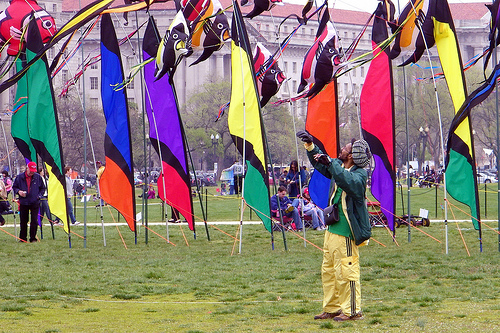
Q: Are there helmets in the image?
A: No, there are no helmets.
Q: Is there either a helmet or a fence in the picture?
A: No, there are no helmets or fences.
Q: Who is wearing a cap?
A: The man is wearing a cap.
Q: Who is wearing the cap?
A: The man is wearing a cap.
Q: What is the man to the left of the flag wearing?
A: The man is wearing a cap.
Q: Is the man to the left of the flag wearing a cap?
A: Yes, the man is wearing a cap.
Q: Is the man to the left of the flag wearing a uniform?
A: No, the man is wearing a cap.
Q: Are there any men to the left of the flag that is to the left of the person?
A: Yes, there is a man to the left of the flag.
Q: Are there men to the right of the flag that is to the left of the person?
A: No, the man is to the left of the flag.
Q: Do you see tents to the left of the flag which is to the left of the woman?
A: No, there is a man to the left of the flag.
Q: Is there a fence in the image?
A: No, there are no fences.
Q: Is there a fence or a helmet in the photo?
A: No, there are no fences or helmets.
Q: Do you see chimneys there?
A: No, there are no chimneys.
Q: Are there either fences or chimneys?
A: No, there are no chimneys or fences.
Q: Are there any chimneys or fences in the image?
A: No, there are no chimneys or fences.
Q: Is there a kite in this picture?
A: Yes, there is a kite.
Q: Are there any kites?
A: Yes, there is a kite.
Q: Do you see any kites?
A: Yes, there is a kite.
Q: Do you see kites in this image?
A: Yes, there is a kite.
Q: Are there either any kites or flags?
A: Yes, there is a kite.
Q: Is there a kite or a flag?
A: Yes, there is a kite.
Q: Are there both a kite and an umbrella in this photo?
A: No, there is a kite but no umbrellas.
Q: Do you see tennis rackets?
A: No, there are no tennis rackets.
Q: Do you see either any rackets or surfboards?
A: No, there are no rackets or surfboards.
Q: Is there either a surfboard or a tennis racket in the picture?
A: No, there are no rackets or surfboards.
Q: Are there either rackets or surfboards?
A: No, there are no rackets or surfboards.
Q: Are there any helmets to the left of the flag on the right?
A: No, there is a kite to the left of the flag.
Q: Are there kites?
A: Yes, there is a kite.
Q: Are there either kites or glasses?
A: Yes, there is a kite.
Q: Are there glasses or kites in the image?
A: Yes, there is a kite.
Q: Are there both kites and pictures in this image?
A: No, there is a kite but no pictures.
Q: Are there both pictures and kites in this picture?
A: No, there is a kite but no pictures.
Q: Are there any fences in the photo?
A: No, there are no fences.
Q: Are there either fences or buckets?
A: No, there are no fences or buckets.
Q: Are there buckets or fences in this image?
A: No, there are no fences or buckets.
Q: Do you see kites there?
A: Yes, there is a kite.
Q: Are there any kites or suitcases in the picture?
A: Yes, there is a kite.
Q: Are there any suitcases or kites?
A: Yes, there is a kite.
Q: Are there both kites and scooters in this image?
A: No, there is a kite but no scooters.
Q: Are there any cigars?
A: No, there are no cigars.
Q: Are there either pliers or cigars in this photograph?
A: No, there are no cigars or pliers.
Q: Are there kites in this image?
A: Yes, there is a kite.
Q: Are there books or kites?
A: Yes, there is a kite.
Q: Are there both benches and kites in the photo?
A: Yes, there are both a kite and a bench.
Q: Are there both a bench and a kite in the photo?
A: Yes, there are both a kite and a bench.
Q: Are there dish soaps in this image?
A: No, there are no dish soaps.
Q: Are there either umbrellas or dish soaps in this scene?
A: No, there are no dish soaps or umbrellas.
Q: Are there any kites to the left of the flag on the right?
A: Yes, there is a kite to the left of the flag.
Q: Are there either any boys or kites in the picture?
A: Yes, there is a kite.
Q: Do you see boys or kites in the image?
A: Yes, there is a kite.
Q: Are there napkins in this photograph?
A: No, there are no napkins.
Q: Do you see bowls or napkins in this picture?
A: No, there are no napkins or bowls.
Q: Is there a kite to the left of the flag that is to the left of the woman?
A: Yes, there is a kite to the left of the flag.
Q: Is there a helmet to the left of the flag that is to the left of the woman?
A: No, there is a kite to the left of the flag.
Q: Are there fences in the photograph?
A: No, there are no fences.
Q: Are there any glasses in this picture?
A: No, there are no glasses.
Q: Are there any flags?
A: Yes, there is a flag.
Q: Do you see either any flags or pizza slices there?
A: Yes, there is a flag.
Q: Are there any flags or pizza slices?
A: Yes, there is a flag.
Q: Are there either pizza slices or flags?
A: Yes, there is a flag.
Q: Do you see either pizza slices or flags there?
A: Yes, there is a flag.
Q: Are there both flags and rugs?
A: No, there is a flag but no rugs.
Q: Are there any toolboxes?
A: No, there are no toolboxes.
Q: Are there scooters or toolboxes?
A: No, there are no toolboxes or scooters.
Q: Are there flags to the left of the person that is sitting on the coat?
A: Yes, there is a flag to the left of the person.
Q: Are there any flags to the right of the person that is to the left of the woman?
A: No, the flag is to the left of the person.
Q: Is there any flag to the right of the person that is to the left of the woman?
A: No, the flag is to the left of the person.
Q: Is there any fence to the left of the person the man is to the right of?
A: No, there is a flag to the left of the person.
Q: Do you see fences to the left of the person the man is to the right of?
A: No, there is a flag to the left of the person.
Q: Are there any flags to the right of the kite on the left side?
A: Yes, there is a flag to the right of the kite.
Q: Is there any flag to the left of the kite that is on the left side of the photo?
A: No, the flag is to the right of the kite.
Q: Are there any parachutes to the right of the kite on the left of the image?
A: No, there is a flag to the right of the kite.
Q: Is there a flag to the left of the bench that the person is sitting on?
A: Yes, there is a flag to the left of the bench.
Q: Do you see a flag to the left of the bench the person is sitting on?
A: Yes, there is a flag to the left of the bench.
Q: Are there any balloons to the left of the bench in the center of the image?
A: No, there is a flag to the left of the bench.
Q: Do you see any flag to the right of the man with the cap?
A: Yes, there is a flag to the right of the man.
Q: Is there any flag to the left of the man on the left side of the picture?
A: No, the flag is to the right of the man.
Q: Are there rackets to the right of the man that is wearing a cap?
A: No, there is a flag to the right of the man.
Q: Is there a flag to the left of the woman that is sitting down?
A: Yes, there is a flag to the left of the woman.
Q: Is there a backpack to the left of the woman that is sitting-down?
A: No, there is a flag to the left of the woman.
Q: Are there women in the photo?
A: Yes, there is a woman.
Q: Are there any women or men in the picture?
A: Yes, there is a woman.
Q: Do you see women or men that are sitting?
A: Yes, the woman is sitting.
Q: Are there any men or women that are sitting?
A: Yes, the woman is sitting.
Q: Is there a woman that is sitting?
A: Yes, there is a woman that is sitting.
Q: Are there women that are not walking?
A: Yes, there is a woman that is sitting.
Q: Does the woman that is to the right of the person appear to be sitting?
A: Yes, the woman is sitting.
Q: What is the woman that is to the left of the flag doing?
A: The woman is sitting.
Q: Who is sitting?
A: The woman is sitting.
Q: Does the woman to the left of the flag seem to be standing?
A: No, the woman is sitting.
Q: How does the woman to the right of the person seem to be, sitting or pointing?
A: The woman is sitting.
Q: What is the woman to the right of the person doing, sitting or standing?
A: The woman is sitting.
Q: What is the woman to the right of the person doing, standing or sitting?
A: The woman is sitting.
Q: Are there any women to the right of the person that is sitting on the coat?
A: Yes, there is a woman to the right of the person.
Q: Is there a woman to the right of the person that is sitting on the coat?
A: Yes, there is a woman to the right of the person.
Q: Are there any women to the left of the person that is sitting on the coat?
A: No, the woman is to the right of the person.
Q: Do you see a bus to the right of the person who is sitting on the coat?
A: No, there is a woman to the right of the person.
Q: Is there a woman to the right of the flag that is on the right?
A: No, the woman is to the left of the flag.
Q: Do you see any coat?
A: Yes, there is a coat.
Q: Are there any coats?
A: Yes, there is a coat.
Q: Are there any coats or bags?
A: Yes, there is a coat.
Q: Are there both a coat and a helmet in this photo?
A: No, there is a coat but no helmets.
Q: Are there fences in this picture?
A: No, there are no fences.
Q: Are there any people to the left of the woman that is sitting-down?
A: Yes, there is a person to the left of the woman.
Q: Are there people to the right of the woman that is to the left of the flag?
A: No, the person is to the left of the woman.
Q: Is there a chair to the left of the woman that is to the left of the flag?
A: No, there is a person to the left of the woman.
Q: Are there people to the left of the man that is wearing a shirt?
A: Yes, there is a person to the left of the man.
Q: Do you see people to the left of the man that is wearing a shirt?
A: Yes, there is a person to the left of the man.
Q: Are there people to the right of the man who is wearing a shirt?
A: No, the person is to the left of the man.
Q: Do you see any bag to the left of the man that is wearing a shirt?
A: No, there is a person to the left of the man.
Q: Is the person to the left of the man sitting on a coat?
A: Yes, the person is sitting on a coat.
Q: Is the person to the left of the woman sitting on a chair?
A: No, the person is sitting on a coat.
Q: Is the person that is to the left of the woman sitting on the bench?
A: Yes, the person is sitting on the bench.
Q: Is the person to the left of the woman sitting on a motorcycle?
A: No, the person is sitting on the bench.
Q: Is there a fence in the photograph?
A: No, there are no fences.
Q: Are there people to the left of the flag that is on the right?
A: Yes, there is a person to the left of the flag.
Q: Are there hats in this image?
A: Yes, there is a hat.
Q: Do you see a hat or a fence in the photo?
A: Yes, there is a hat.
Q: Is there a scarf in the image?
A: No, there are no scarves.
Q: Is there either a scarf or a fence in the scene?
A: No, there are no scarves or fences.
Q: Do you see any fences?
A: No, there are no fences.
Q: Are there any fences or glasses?
A: No, there are no fences or glasses.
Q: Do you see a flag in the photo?
A: Yes, there is a flag.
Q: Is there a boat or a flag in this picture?
A: Yes, there is a flag.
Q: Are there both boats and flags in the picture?
A: No, there is a flag but no boats.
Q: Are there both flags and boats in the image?
A: No, there is a flag but no boats.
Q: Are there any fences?
A: No, there are no fences.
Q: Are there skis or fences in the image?
A: No, there are no fences or skis.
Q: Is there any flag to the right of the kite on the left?
A: Yes, there is a flag to the right of the kite.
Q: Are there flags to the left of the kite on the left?
A: No, the flag is to the right of the kite.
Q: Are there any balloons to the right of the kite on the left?
A: No, there is a flag to the right of the kite.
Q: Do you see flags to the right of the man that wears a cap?
A: Yes, there is a flag to the right of the man.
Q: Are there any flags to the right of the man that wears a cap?
A: Yes, there is a flag to the right of the man.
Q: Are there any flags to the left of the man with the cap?
A: No, the flag is to the right of the man.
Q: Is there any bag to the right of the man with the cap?
A: No, there is a flag to the right of the man.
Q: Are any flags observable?
A: Yes, there is a flag.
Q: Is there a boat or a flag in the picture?
A: Yes, there is a flag.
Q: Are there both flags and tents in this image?
A: No, there is a flag but no tents.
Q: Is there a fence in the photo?
A: No, there are no fences.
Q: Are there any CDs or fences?
A: No, there are no fences or cds.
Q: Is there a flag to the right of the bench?
A: Yes, there is a flag to the right of the bench.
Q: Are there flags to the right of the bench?
A: Yes, there is a flag to the right of the bench.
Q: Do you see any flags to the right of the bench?
A: Yes, there is a flag to the right of the bench.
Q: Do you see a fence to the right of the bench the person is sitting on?
A: No, there is a flag to the right of the bench.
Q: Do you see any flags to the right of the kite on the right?
A: Yes, there is a flag to the right of the kite.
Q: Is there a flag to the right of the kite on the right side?
A: Yes, there is a flag to the right of the kite.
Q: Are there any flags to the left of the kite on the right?
A: No, the flag is to the right of the kite.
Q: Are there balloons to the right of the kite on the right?
A: No, there is a flag to the right of the kite.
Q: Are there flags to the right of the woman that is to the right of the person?
A: Yes, there is a flag to the right of the woman.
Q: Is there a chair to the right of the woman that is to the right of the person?
A: No, there is a flag to the right of the woman.